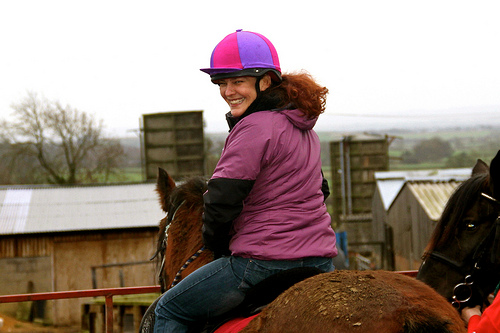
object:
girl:
[141, 20, 340, 331]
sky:
[0, 0, 498, 137]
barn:
[323, 129, 484, 273]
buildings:
[321, 130, 480, 271]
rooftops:
[350, 152, 499, 275]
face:
[421, 150, 500, 304]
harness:
[166, 246, 208, 282]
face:
[145, 165, 204, 283]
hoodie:
[195, 97, 338, 261]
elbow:
[204, 180, 249, 228]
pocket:
[228, 254, 249, 282]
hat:
[199, 29, 282, 80]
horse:
[156, 165, 467, 331]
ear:
[155, 165, 175, 211]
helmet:
[201, 28, 278, 83]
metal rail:
[0, 266, 425, 331]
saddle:
[207, 311, 254, 332]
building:
[0, 107, 209, 333]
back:
[260, 269, 470, 332]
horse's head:
[417, 150, 498, 309]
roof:
[3, 184, 187, 231]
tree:
[0, 89, 105, 184]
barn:
[1, 110, 216, 327]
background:
[1, 0, 499, 191]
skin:
[226, 70, 247, 99]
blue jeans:
[138, 254, 331, 332]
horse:
[416, 149, 500, 305]